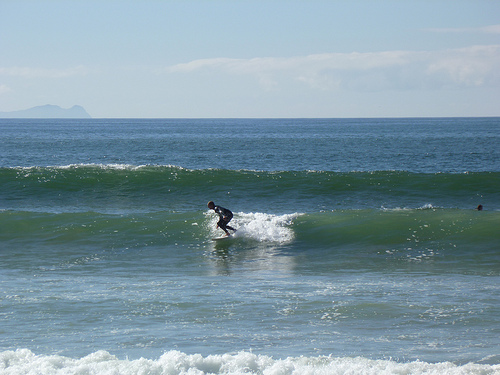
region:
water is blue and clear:
[321, 205, 496, 368]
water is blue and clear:
[81, 241, 328, 346]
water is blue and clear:
[36, 210, 131, 352]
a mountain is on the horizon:
[0, 92, 93, 133]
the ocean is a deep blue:
[3, 120, 495, 160]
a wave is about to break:
[0, 155, 495, 205]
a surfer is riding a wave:
[198, 193, 243, 253]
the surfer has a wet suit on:
[198, 193, 243, 249]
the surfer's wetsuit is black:
[210, 203, 237, 234]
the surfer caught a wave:
[80, 195, 396, 256]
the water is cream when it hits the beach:
[2, 340, 497, 373]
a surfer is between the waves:
[447, 156, 490, 228]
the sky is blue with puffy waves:
[6, 1, 494, 114]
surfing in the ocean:
[204, 200, 243, 243]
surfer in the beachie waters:
[204, 199, 248, 241]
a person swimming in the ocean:
[459, 194, 489, 220]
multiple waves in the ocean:
[24, 148, 166, 243]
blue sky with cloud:
[171, 31, 480, 110]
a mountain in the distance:
[0, 98, 100, 129]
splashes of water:
[329, 201, 434, 250]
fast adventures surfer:
[197, 194, 252, 247]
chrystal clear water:
[47, 286, 208, 353]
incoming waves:
[72, 333, 242, 373]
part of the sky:
[299, 0, 365, 54]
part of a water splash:
[251, 219, 302, 254]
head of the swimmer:
[200, 195, 217, 212]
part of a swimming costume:
[220, 202, 236, 219]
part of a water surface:
[345, 262, 395, 338]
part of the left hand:
[213, 207, 235, 223]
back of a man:
[216, 203, 228, 212]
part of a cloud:
[332, 55, 389, 95]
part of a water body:
[276, 108, 326, 140]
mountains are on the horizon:
[0, 97, 97, 132]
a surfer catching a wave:
[203, 195, 249, 250]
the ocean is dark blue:
[2, 117, 494, 155]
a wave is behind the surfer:
[5, 155, 496, 200]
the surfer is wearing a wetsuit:
[203, 198, 234, 240]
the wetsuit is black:
[208, 202, 236, 242]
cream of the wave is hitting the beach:
[5, 337, 497, 372]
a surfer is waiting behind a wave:
[468, 197, 485, 217]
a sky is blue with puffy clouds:
[10, 6, 495, 93]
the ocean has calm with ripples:
[2, 119, 499, 153]